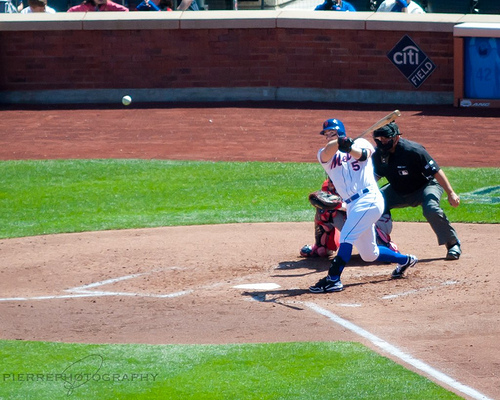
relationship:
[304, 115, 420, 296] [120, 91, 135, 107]
baseball player hit ball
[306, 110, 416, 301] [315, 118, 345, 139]
batter wearing blue helmet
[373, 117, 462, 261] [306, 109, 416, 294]
catcher standing behind batter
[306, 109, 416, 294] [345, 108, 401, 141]
batter holding bat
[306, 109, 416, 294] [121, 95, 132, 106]
batter hit ball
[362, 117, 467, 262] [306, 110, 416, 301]
catcher squatting behind batter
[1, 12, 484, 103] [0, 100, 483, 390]
brick wall behind field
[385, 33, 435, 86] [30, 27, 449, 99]
citi-field-sign on wall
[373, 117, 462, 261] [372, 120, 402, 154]
catcher wearing facemask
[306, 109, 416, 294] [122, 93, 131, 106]
batter hitting baseball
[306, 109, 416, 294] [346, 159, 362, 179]
batter with number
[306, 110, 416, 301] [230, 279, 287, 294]
batter behind home plate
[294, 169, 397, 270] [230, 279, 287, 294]
catcher behind home plate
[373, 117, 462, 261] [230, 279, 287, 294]
catcher behind home plate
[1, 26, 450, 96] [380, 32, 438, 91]
short/brick wall with sign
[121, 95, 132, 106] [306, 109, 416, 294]
ball hit by batter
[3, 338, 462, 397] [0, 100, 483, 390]
grass on field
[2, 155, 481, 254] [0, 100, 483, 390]
grass on field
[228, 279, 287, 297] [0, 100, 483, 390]
home plate on field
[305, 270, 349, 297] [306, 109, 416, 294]
shoe of batter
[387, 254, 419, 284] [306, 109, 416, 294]
shoe of batter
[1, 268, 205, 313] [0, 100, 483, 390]
line on field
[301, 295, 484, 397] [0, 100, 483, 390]
line on field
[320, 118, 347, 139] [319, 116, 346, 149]
blue helmet on head